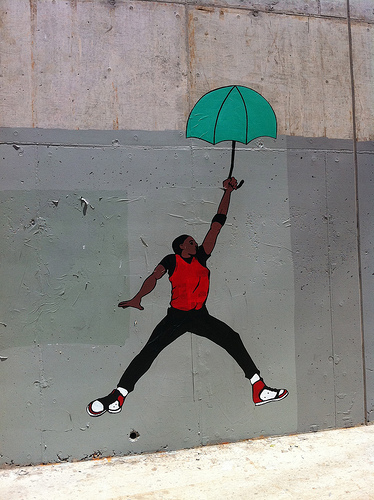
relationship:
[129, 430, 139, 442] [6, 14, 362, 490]
hole in wall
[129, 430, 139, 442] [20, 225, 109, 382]
hole on wall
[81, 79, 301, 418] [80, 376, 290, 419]
drawing wearing shoes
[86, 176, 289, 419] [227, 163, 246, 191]
man holding umbrella handle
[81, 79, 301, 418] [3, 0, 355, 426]
drawing on wall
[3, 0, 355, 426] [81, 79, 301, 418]
wall on drawing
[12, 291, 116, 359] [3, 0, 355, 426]
section of wall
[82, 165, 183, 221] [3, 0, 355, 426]
section of wall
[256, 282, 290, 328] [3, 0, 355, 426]
section of wall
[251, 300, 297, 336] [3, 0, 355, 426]
section of wall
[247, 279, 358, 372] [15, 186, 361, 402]
section of wall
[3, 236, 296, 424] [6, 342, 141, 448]
section of wall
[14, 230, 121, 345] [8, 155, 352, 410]
section of wall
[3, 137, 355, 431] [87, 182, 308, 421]
picture of a man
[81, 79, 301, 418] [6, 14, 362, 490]
drawing on the wall